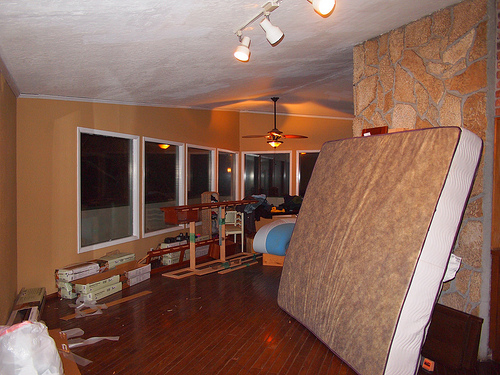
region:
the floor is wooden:
[237, 326, 248, 351]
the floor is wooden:
[244, 338, 259, 363]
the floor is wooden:
[247, 360, 260, 371]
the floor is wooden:
[239, 343, 247, 352]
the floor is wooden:
[225, 323, 239, 348]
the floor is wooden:
[214, 328, 226, 350]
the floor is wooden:
[225, 348, 242, 366]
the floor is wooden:
[218, 333, 233, 348]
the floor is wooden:
[222, 345, 235, 353]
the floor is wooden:
[237, 341, 254, 358]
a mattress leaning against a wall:
[270, 124, 490, 373]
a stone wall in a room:
[352, 0, 486, 313]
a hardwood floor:
[36, 263, 358, 373]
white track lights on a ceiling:
[226, 2, 343, 72]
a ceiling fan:
[229, 89, 323, 154]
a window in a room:
[70, 124, 143, 253]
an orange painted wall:
[17, 97, 243, 303]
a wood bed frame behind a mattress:
[420, 299, 486, 371]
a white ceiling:
[1, 1, 457, 107]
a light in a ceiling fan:
[268, 138, 282, 152]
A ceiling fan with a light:
[243, 97, 313, 153]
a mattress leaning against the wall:
[264, 127, 489, 373]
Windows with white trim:
[72, 120, 184, 251]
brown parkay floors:
[194, 305, 274, 357]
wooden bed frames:
[165, 200, 268, 281]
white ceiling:
[74, 23, 199, 75]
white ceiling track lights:
[228, 0, 353, 62]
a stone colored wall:
[387, 40, 480, 120]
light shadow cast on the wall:
[209, 90, 352, 130]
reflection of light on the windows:
[152, 132, 241, 183]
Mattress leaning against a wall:
[277, 122, 485, 374]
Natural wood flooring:
[178, 297, 245, 363]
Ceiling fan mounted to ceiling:
[237, 83, 312, 153]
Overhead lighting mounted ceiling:
[225, 6, 286, 68]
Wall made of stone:
[375, 48, 490, 109]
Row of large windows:
[70, 121, 238, 263]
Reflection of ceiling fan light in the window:
[158, 143, 173, 156]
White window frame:
[74, 121, 142, 254]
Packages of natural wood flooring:
[52, 253, 155, 315]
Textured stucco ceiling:
[102, 61, 196, 93]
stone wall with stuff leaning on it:
[350, 3, 496, 369]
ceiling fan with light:
[239, 91, 312, 159]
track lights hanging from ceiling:
[203, 0, 383, 62]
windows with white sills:
[65, 123, 340, 256]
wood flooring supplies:
[45, 250, 158, 308]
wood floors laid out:
[69, 259, 334, 374]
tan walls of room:
[2, 90, 355, 316]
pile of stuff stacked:
[219, 191, 305, 258]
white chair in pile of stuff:
[215, 208, 246, 260]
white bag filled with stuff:
[1, 315, 63, 373]